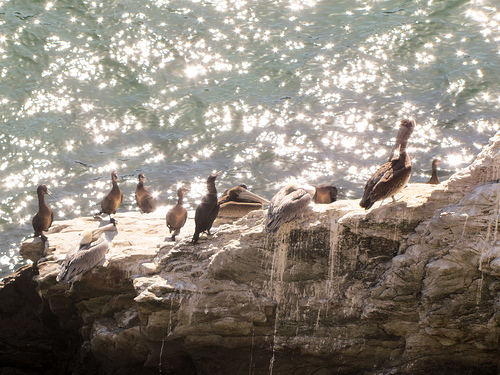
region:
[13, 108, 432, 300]
a group of birds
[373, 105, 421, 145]
face of the bird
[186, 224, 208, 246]
tail of the bird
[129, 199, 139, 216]
leg of the bird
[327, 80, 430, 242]
a bird in the rock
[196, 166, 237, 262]
black bird in the stone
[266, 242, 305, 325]
white mark in rock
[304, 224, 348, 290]
white mark in stone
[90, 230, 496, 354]
a clear view of mountain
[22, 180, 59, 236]
brown bird on hill side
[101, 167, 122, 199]
brown bird on hill side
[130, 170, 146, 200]
brown bird on hill side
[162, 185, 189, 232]
brown bird on hill side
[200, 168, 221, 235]
brown bird on hill side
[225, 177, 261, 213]
brown bird on hill side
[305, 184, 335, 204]
brown bird on hill side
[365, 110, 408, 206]
brown bird on hill side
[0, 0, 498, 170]
water down below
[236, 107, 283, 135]
this is sun reflecting on water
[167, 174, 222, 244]
two birds stand together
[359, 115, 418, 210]
a bird standing alone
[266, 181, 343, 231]
a bird bent over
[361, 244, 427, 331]
ridges on rocks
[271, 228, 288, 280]
bird feces on rocks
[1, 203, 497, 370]
a brownish white rock cliff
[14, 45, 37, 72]
ripples in the water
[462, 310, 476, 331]
part of a rock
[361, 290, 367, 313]
part of a crack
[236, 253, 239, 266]
part of a hill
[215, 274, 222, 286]
side of a rock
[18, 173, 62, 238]
brown bird near gray water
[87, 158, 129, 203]
brown bird near gray water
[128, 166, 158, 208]
brown bird near gray water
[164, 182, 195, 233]
brown bird near gray water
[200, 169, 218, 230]
brown bird near gray water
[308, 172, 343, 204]
brown bird near gray water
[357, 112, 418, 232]
brown bird near gray water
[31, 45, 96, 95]
ripples in gray water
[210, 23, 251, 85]
ripples in gray water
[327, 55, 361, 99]
ripples in gray water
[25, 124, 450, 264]
birds standing on the rocks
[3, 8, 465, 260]
green water beside the rocks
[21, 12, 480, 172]
sunlight on the water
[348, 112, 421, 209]
bird with brown body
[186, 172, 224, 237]
black bird on the stone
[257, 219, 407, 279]
black staining on the rock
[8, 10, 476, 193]
ripples in the water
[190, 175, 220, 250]
A bird on a rock.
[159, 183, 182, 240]
A bird on a rock.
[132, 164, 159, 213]
A bird on a rock.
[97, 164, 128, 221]
A bird on a rock.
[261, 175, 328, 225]
A bird on a rock.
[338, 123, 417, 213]
A bird on a rock.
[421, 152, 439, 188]
A bird on a rock.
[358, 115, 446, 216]
A bird on a rock.